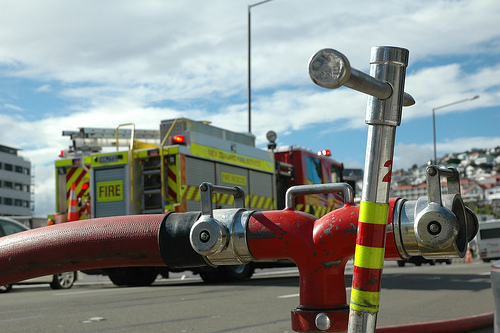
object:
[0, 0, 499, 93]
clouds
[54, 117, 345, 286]
fire truck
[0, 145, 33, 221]
building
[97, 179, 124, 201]
sign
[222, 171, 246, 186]
sign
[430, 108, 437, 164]
pole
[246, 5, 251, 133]
pole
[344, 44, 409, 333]
pole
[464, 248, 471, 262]
cone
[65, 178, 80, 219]
cone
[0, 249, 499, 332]
street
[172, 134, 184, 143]
light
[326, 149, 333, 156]
light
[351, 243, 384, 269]
tape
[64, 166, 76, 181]
stripes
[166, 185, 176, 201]
stripes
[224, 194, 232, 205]
stripes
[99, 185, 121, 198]
lettering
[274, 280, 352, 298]
line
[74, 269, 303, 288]
line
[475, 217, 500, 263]
van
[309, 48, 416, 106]
screw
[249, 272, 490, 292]
shadow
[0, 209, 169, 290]
fire hose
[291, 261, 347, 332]
pipe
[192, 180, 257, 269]
connector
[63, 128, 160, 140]
ladder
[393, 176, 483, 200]
houses